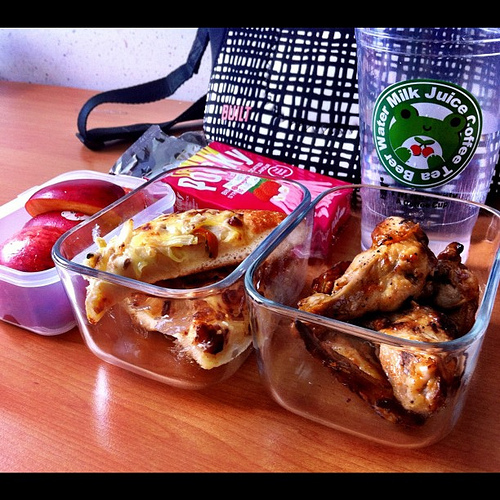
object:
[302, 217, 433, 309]
wing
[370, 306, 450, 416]
wing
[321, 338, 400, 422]
wing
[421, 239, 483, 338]
wing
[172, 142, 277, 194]
pocky snacks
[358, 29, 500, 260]
tumbler glass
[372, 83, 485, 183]
icon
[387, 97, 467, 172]
green animal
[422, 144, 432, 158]
small fruit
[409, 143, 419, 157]
small fruit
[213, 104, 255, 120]
"built"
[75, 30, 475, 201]
lunch bag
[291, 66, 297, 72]
white background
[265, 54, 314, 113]
crisscrossing lines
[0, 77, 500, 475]
countertop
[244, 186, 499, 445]
container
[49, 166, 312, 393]
container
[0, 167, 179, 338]
container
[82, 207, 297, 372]
chicken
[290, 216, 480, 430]
chicken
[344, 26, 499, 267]
cup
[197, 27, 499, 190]
bag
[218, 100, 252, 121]
letters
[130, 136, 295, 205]
sticks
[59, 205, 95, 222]
sticker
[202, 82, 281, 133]
letting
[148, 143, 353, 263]
box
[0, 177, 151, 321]
apple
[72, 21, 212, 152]
strap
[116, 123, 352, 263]
satchet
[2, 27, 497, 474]
table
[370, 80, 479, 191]
emblem